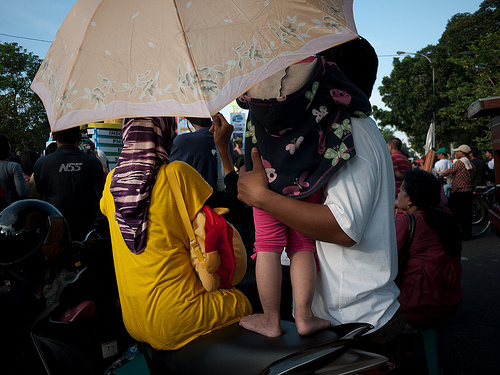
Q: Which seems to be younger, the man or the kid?
A: The kid is younger than the man.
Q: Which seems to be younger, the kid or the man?
A: The kid is younger than the man.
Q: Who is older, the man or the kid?
A: The man is older than the kid.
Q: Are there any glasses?
A: No, there are no glasses.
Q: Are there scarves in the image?
A: Yes, there is a scarf.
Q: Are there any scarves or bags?
A: Yes, there is a scarf.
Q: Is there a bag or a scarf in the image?
A: Yes, there is a scarf.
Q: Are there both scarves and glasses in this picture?
A: No, there is a scarf but no glasses.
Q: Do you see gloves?
A: No, there are no gloves.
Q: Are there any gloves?
A: No, there are no gloves.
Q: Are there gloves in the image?
A: No, there are no gloves.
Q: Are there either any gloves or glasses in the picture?
A: No, there are no gloves or glasses.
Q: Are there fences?
A: No, there are no fences.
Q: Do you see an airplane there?
A: No, there are no airplanes.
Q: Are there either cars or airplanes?
A: No, there are no airplanes or cars.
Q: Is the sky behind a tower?
A: No, the sky is behind an umbrella.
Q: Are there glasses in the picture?
A: No, there are no glasses.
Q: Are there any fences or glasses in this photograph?
A: No, there are no glasses or fences.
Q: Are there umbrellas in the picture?
A: Yes, there is an umbrella.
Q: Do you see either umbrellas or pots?
A: Yes, there is an umbrella.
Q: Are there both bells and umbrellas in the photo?
A: No, there is an umbrella but no bells.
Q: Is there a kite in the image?
A: No, there are no kites.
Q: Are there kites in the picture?
A: No, there are no kites.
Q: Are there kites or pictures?
A: No, there are no kites or pictures.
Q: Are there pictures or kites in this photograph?
A: No, there are no kites or pictures.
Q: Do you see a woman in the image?
A: Yes, there is a woman.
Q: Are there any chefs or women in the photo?
A: Yes, there is a woman.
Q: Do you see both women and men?
A: Yes, there are both a woman and men.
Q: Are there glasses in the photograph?
A: No, there are no glasses.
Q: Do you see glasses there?
A: No, there are no glasses.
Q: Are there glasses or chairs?
A: No, there are no glasses or chairs.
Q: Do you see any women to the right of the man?
A: Yes, there is a woman to the right of the man.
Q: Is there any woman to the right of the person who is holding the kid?
A: Yes, there is a woman to the right of the man.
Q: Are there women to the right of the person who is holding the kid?
A: Yes, there is a woman to the right of the man.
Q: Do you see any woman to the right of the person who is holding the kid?
A: Yes, there is a woman to the right of the man.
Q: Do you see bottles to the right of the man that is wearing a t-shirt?
A: No, there is a woman to the right of the man.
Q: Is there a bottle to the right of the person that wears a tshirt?
A: No, there is a woman to the right of the man.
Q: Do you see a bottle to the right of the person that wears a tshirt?
A: No, there is a woman to the right of the man.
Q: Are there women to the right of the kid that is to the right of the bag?
A: Yes, there is a woman to the right of the kid.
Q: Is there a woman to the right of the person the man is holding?
A: Yes, there is a woman to the right of the kid.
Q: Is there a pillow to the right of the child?
A: No, there is a woman to the right of the child.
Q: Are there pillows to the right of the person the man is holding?
A: No, there is a woman to the right of the child.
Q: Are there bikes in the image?
A: Yes, there is a bike.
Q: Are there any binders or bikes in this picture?
A: Yes, there is a bike.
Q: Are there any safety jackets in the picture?
A: No, there are no safety jackets.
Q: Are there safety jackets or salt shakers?
A: No, there are no safety jackets or salt shakers.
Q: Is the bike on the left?
A: Yes, the bike is on the left of the image.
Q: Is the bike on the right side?
A: No, the bike is on the left of the image.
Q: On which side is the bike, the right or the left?
A: The bike is on the left of the image.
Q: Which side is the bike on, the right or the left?
A: The bike is on the left of the image.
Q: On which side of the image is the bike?
A: The bike is on the left of the image.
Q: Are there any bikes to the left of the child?
A: Yes, there is a bike to the left of the child.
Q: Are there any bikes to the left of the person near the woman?
A: Yes, there is a bike to the left of the child.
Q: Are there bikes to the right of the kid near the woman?
A: No, the bike is to the left of the kid.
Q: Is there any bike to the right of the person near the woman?
A: No, the bike is to the left of the kid.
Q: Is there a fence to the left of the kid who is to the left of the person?
A: No, there is a bike to the left of the child.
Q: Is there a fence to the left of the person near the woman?
A: No, there is a bike to the left of the child.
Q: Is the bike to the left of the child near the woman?
A: Yes, the bike is to the left of the child.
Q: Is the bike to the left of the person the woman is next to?
A: Yes, the bike is to the left of the child.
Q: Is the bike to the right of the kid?
A: No, the bike is to the left of the kid.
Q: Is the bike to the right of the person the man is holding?
A: No, the bike is to the left of the kid.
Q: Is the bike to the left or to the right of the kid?
A: The bike is to the left of the kid.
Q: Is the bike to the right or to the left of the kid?
A: The bike is to the left of the kid.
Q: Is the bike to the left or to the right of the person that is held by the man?
A: The bike is to the left of the kid.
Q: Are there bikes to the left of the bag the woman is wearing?
A: Yes, there is a bike to the left of the bag.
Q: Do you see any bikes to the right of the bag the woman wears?
A: No, the bike is to the left of the bag.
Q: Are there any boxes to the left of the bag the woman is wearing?
A: No, there is a bike to the left of the bag.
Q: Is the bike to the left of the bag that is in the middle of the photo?
A: Yes, the bike is to the left of the bag.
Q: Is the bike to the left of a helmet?
A: No, the bike is to the left of the bag.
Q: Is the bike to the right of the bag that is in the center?
A: No, the bike is to the left of the bag.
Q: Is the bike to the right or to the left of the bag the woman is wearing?
A: The bike is to the left of the bag.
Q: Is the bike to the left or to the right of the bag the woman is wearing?
A: The bike is to the left of the bag.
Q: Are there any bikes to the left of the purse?
A: Yes, there is a bike to the left of the purse.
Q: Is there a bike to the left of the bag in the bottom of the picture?
A: Yes, there is a bike to the left of the purse.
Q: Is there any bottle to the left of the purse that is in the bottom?
A: No, there is a bike to the left of the purse.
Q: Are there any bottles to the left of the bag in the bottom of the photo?
A: No, there is a bike to the left of the purse.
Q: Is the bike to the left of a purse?
A: Yes, the bike is to the left of a purse.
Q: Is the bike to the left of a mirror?
A: No, the bike is to the left of a purse.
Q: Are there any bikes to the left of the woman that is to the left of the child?
A: Yes, there is a bike to the left of the woman.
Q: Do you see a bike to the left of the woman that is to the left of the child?
A: Yes, there is a bike to the left of the woman.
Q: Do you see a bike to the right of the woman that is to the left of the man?
A: No, the bike is to the left of the woman.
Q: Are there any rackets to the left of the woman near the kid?
A: No, there is a bike to the left of the woman.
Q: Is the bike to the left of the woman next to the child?
A: Yes, the bike is to the left of the woman.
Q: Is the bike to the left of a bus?
A: No, the bike is to the left of the woman.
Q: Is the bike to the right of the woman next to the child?
A: No, the bike is to the left of the woman.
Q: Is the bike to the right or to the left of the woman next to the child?
A: The bike is to the left of the woman.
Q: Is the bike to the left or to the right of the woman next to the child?
A: The bike is to the left of the woman.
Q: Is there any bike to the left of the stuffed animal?
A: Yes, there is a bike to the left of the stuffed animal.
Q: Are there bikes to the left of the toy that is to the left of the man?
A: Yes, there is a bike to the left of the stuffed animal.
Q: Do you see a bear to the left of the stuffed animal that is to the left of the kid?
A: No, there is a bike to the left of the stuffed animal.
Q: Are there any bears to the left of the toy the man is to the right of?
A: No, there is a bike to the left of the stuffed animal.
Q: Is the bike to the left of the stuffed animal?
A: Yes, the bike is to the left of the stuffed animal.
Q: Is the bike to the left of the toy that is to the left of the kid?
A: Yes, the bike is to the left of the stuffed animal.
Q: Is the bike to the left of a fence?
A: No, the bike is to the left of the stuffed animal.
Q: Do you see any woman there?
A: Yes, there is a woman.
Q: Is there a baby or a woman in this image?
A: Yes, there is a woman.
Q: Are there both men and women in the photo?
A: Yes, there are both a woman and a man.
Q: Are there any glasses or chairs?
A: No, there are no glasses or chairs.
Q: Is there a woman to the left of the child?
A: Yes, there is a woman to the left of the child.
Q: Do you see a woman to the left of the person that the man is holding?
A: Yes, there is a woman to the left of the child.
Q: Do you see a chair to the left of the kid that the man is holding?
A: No, there is a woman to the left of the child.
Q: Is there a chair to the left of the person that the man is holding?
A: No, there is a woman to the left of the child.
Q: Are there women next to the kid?
A: Yes, there is a woman next to the kid.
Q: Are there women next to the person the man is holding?
A: Yes, there is a woman next to the kid.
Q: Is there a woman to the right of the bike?
A: Yes, there is a woman to the right of the bike.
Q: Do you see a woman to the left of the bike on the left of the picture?
A: No, the woman is to the right of the bike.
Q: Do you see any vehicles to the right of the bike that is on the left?
A: No, there is a woman to the right of the bike.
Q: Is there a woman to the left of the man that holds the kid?
A: Yes, there is a woman to the left of the man.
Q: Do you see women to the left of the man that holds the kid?
A: Yes, there is a woman to the left of the man.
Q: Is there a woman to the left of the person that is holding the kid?
A: Yes, there is a woman to the left of the man.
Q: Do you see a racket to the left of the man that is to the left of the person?
A: No, there is a woman to the left of the man.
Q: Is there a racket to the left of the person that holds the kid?
A: No, there is a woman to the left of the man.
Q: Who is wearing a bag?
A: The woman is wearing a bag.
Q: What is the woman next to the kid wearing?
A: The woman is wearing a bag.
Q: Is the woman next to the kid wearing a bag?
A: Yes, the woman is wearing a bag.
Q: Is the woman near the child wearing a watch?
A: No, the woman is wearing a bag.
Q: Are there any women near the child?
A: Yes, there is a woman near the child.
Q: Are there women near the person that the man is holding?
A: Yes, there is a woman near the child.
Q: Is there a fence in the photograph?
A: No, there are no fences.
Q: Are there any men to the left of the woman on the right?
A: Yes, there is a man to the left of the woman.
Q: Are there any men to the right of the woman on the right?
A: No, the man is to the left of the woman.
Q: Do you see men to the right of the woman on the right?
A: No, the man is to the left of the woman.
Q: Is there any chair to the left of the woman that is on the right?
A: No, there is a man to the left of the woman.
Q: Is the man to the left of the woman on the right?
A: Yes, the man is to the left of the woman.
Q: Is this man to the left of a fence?
A: No, the man is to the left of the woman.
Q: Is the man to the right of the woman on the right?
A: No, the man is to the left of the woman.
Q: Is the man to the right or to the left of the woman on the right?
A: The man is to the left of the woman.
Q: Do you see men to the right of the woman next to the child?
A: Yes, there is a man to the right of the woman.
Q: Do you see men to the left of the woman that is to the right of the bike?
A: No, the man is to the right of the woman.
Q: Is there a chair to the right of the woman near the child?
A: No, there is a man to the right of the woman.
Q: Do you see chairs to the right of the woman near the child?
A: No, there is a man to the right of the woman.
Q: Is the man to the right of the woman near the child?
A: Yes, the man is to the right of the woman.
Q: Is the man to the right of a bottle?
A: No, the man is to the right of the woman.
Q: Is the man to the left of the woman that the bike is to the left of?
A: No, the man is to the right of the woman.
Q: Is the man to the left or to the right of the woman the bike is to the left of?
A: The man is to the right of the woman.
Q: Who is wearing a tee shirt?
A: The man is wearing a tee shirt.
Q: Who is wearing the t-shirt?
A: The man is wearing a tee shirt.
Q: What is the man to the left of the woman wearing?
A: The man is wearing a t-shirt.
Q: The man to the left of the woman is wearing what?
A: The man is wearing a t-shirt.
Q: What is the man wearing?
A: The man is wearing a t-shirt.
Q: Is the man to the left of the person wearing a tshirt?
A: Yes, the man is wearing a tshirt.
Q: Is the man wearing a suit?
A: No, the man is wearing a tshirt.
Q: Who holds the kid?
A: The man holds the kid.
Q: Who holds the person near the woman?
A: The man holds the kid.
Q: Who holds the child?
A: The man holds the kid.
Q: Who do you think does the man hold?
A: The man holds the kid.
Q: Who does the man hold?
A: The man holds the kid.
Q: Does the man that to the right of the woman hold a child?
A: Yes, the man holds a child.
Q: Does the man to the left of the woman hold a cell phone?
A: No, the man holds a child.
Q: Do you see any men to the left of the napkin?
A: Yes, there is a man to the left of the napkin.